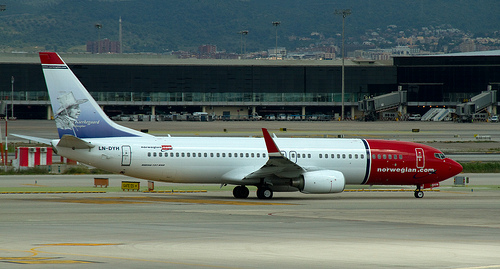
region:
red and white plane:
[37, 45, 468, 207]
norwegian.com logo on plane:
[372, 160, 438, 176]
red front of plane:
[358, 135, 463, 190]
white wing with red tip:
[235, 115, 307, 195]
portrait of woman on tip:
[35, 67, 130, 137]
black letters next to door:
[95, 140, 121, 150]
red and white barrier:
[7, 140, 92, 170]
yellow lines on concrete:
[5, 220, 136, 265]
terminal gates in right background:
[350, 71, 496, 116]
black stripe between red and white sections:
[358, 137, 375, 187]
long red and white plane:
[34, 45, 467, 209]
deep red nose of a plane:
[349, 126, 465, 222]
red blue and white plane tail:
[5, 20, 161, 187]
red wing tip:
[239, 114, 294, 177]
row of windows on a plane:
[139, 141, 411, 167]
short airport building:
[40, 41, 489, 127]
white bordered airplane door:
[407, 139, 429, 175]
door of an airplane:
[110, 139, 144, 176]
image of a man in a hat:
[39, 82, 105, 151]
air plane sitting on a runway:
[31, 43, 472, 231]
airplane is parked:
[8, 50, 463, 197]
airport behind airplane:
[0, 49, 499, 122]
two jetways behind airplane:
[356, 85, 496, 123]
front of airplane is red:
[363, 137, 463, 185]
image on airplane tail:
[54, 90, 101, 130]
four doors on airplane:
[121, 144, 424, 168]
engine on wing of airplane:
[290, 168, 344, 192]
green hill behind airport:
[0, 0, 499, 58]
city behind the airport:
[85, 22, 498, 59]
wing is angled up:
[219, 125, 306, 191]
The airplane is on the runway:
[1, 47, 498, 267]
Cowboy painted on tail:
[47, 88, 102, 134]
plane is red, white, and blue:
[36, 49, 464, 200]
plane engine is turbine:
[259, 162, 347, 196]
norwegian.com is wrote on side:
[373, 163, 436, 176]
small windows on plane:
[144, 150, 405, 159]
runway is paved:
[2, 150, 497, 266]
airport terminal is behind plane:
[1, 50, 498, 132]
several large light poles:
[92, 1, 354, 60]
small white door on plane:
[120, 142, 133, 171]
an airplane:
[21, 25, 456, 210]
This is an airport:
[7, 16, 496, 210]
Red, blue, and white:
[23, 33, 463, 225]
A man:
[37, 67, 110, 142]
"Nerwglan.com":
[369, 156, 445, 178]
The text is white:
[372, 152, 444, 186]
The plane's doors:
[268, 137, 308, 163]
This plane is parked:
[18, 32, 484, 237]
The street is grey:
[111, 200, 345, 257]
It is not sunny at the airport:
[11, 3, 427, 118]